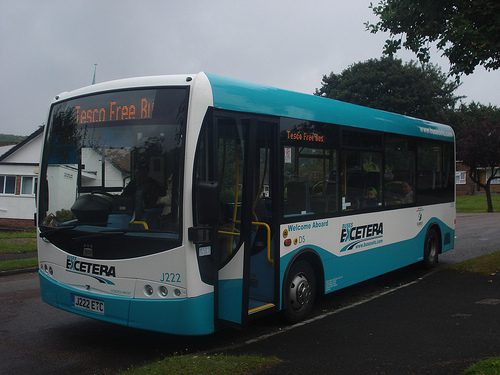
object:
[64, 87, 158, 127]
tesco free bus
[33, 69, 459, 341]
bus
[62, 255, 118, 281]
excetera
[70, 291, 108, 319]
plate j222 etc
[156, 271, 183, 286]
j222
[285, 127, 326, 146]
tesco free bus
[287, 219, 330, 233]
welcome aboard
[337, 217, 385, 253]
excetera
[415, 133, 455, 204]
passenger windows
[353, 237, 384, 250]
website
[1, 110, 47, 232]
house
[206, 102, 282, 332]
bus door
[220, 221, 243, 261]
hand rails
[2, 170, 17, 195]
windows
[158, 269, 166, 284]
letter j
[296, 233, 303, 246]
letter d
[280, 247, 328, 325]
tire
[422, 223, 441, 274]
tire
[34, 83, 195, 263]
windshield window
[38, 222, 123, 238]
windshield wipers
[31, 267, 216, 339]
front bumper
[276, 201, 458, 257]
stripe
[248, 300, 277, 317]
step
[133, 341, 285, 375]
grass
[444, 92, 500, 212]
trees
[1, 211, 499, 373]
street